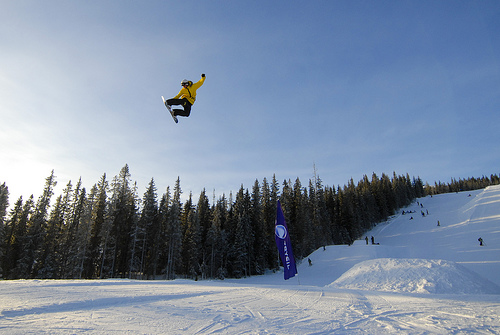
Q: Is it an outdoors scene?
A: Yes, it is outdoors.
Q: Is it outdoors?
A: Yes, it is outdoors.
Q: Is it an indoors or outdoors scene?
A: It is outdoors.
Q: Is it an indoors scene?
A: No, it is outdoors.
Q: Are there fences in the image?
A: No, there are no fences.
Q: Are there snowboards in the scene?
A: Yes, there is a snowboard.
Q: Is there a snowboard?
A: Yes, there is a snowboard.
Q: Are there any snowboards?
A: Yes, there is a snowboard.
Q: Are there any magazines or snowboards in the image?
A: Yes, there is a snowboard.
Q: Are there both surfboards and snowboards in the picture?
A: No, there is a snowboard but no surfboards.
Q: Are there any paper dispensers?
A: No, there are no paper dispensers.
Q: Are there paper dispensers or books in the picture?
A: No, there are no paper dispensers or books.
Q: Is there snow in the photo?
A: Yes, there is snow.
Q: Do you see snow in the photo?
A: Yes, there is snow.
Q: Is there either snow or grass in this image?
A: Yes, there is snow.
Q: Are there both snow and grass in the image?
A: No, there is snow but no grass.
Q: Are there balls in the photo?
A: No, there are no balls.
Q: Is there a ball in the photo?
A: No, there are no balls.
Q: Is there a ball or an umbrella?
A: No, there are no balls or umbrellas.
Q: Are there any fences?
A: No, there are no fences.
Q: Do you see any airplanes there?
A: No, there are no airplanes.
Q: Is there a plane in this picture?
A: No, there are no airplanes.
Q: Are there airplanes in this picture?
A: No, there are no airplanes.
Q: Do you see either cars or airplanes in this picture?
A: No, there are no airplanes or cars.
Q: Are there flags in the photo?
A: Yes, there is a flag.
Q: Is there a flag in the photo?
A: Yes, there is a flag.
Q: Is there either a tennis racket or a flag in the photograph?
A: Yes, there is a flag.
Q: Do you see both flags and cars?
A: No, there is a flag but no cars.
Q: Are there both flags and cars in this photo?
A: No, there is a flag but no cars.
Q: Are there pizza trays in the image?
A: No, there are no pizza trays.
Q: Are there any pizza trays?
A: No, there are no pizza trays.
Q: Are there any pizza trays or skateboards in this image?
A: No, there are no pizza trays or skateboards.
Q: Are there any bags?
A: No, there are no bags.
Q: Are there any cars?
A: No, there are no cars.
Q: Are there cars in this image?
A: No, there are no cars.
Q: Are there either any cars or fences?
A: No, there are no cars or fences.